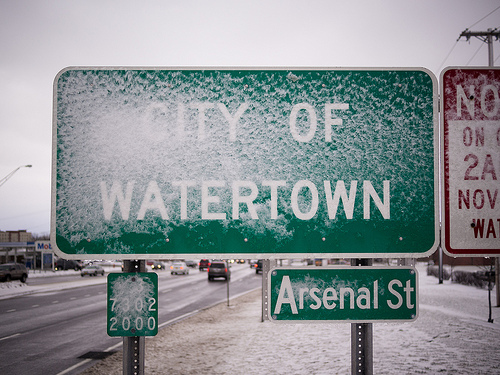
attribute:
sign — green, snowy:
[44, 56, 446, 273]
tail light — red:
[178, 264, 185, 269]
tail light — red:
[168, 265, 174, 270]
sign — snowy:
[204, 257, 438, 349]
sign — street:
[366, 52, 498, 247]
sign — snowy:
[18, 51, 449, 278]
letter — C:
[141, 97, 168, 152]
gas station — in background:
[5, 235, 67, 279]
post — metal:
[346, 254, 381, 368]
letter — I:
[169, 97, 191, 152]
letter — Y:
[219, 99, 252, 146]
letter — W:
[96, 177, 137, 227]